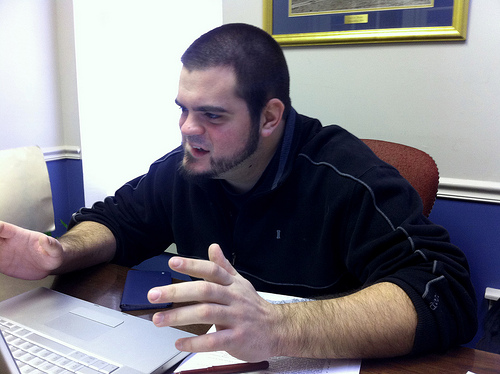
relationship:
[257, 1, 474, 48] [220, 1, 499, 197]
picture on wall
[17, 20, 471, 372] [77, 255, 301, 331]
man sitting at desk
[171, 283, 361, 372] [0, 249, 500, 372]
paper on desk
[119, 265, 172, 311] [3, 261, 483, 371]
book on desk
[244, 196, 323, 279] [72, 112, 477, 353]
zipper on shirt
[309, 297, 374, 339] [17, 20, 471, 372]
hair of man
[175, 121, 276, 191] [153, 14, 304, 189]
beard of face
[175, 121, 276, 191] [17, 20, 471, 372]
beard of man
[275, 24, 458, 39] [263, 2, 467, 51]
frame of picture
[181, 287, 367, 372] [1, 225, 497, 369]
paper on top of table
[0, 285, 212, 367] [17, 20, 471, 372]
laptop in front of man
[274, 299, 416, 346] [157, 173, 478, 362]
hair on arm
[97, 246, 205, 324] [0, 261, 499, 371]
book on table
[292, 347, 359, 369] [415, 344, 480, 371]
papers on table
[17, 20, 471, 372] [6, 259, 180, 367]
man sits by laptop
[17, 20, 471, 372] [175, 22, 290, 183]
man has head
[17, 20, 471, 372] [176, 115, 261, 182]
man has beard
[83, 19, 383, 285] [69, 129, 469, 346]
brunette man wearing sweater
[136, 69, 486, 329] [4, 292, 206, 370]
man staring at laptop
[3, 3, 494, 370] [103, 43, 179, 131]
office has window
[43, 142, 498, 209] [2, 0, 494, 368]
rail around room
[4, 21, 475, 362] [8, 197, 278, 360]
person has hands